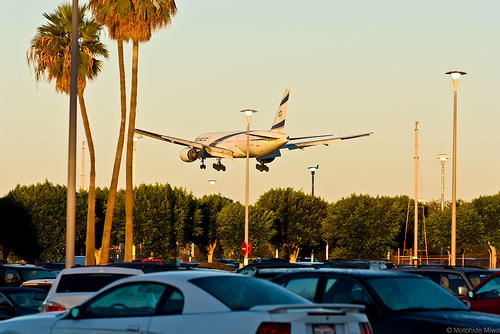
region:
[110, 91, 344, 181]
plane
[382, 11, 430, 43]
white clouds in blue sky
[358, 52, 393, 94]
white clouds in blue sky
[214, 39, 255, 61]
white clouds in blue sky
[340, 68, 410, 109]
white clouds in blue sky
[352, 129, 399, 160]
white clouds in blue sky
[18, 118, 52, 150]
white clouds in blue sky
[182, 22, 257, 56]
white clouds in blue sky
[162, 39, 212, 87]
white clouds in blue sky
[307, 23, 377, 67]
white clouds in blue sky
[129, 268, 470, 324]
cars parked in a lot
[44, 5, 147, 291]
tall palm trees growing in the lot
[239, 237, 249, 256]
do not enter sign on a pole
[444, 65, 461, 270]
light pole in the parking lot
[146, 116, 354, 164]
airplane landing behind the parking lot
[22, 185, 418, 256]
row of trees separating lots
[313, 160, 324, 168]
bird sitting on the light pole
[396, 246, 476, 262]
fence behind the trees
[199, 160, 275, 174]
landing gear on the plane is down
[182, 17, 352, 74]
pale sky above the plane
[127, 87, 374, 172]
an airplane with landing gear extended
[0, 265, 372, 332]
the top of a white sedan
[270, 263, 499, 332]
a dark colored vehicle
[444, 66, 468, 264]
a tall street lamp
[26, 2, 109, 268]
a coconut tree with bent trunk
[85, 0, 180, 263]
a coconut tree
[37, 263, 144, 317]
the back of a white car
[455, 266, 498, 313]
the driver's side view of a red car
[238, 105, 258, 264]
a tall lamp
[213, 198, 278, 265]
a bushy green tree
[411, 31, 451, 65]
white clouds in blue sky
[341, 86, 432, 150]
white clouds in blue sky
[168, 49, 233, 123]
white clouds in blue sky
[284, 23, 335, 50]
white clouds in blue sky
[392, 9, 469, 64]
white clouds in blue sky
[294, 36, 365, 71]
white clouds in blue sky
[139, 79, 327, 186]
large plane is landing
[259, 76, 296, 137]
white and blue tail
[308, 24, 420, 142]
sky is clear and cloudless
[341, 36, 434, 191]
sky is blue and orange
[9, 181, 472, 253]
stand of trees under plane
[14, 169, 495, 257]
trees are green and round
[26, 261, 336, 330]
grey car in parking lot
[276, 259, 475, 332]
blue car in lot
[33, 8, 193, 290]
tall palm trees in lot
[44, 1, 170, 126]
rounded fronds on tree